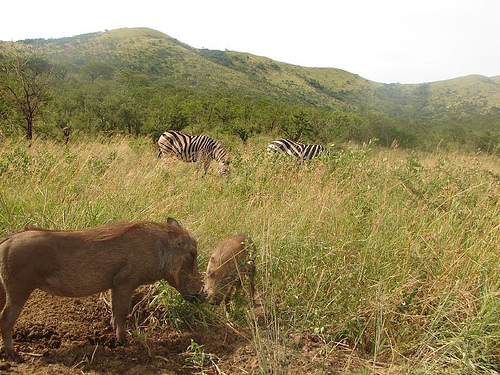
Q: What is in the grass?
A: Animals.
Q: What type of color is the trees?
A: Green.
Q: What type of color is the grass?
A: Brown and green.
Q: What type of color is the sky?
A: White.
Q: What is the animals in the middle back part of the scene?
A: Zebras.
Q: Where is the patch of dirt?
A: In the tall grass.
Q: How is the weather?
A: Clear skies.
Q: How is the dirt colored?
A: Brown.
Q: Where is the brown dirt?
A: Ground.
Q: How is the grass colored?
A: Green.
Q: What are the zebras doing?
A: Grazing.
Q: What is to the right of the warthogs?
A: Yellow and green grass.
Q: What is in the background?
A: Grass covered hills.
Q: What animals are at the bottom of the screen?
A: Warthogs.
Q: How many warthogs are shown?
A: Two.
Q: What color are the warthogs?
A: Brown.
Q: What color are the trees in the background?
A: Green.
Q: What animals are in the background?
A: Zebras.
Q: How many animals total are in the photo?
A: Four.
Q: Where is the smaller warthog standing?
A: In bushes.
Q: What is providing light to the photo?
A: Sun.